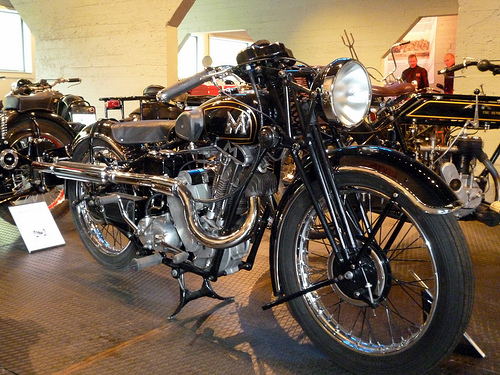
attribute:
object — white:
[13, 200, 59, 252]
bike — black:
[57, 32, 462, 360]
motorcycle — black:
[62, 36, 482, 371]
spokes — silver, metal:
[304, 199, 435, 341]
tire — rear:
[67, 119, 148, 273]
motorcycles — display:
[30, 78, 498, 370]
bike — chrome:
[51, 42, 494, 347]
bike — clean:
[73, 58, 463, 330]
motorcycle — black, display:
[32, 29, 479, 374]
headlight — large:
[309, 52, 376, 144]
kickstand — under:
[135, 271, 234, 311]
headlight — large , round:
[325, 55, 375, 130]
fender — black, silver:
[281, 134, 395, 316]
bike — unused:
[36, 31, 477, 373]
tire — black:
[414, 210, 474, 344]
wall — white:
[33, 24, 178, 122]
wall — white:
[448, 10, 498, 206]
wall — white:
[171, 0, 456, 87]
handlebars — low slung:
[156, 48, 371, 132]